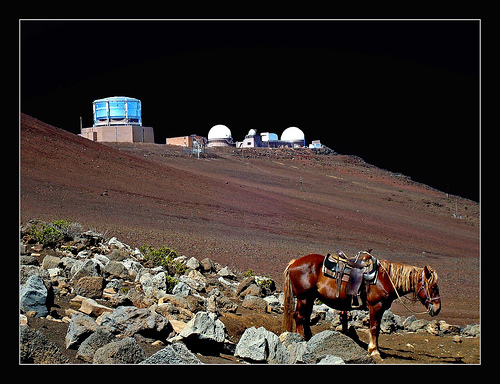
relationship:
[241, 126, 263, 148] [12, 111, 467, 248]
building on dirt hill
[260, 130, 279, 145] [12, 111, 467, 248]
building on dirt hill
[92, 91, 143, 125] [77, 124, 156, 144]
boiler on building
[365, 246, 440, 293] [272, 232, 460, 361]
blonde hair on horse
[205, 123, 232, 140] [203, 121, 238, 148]
globe on buildings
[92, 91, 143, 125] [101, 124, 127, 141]
boiler on building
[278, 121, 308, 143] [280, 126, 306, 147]
globe on buildings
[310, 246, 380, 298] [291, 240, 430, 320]
saddle on horse's back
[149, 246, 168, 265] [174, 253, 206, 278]
bushes in rocks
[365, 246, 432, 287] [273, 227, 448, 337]
blonde hair on horse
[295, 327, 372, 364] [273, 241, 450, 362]
rock surrounding horse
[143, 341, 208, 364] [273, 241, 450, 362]
rock surrounding horse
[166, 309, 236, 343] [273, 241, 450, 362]
rock surrounding horse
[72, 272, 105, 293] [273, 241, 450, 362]
rock surrounding horse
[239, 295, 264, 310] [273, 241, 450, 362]
rock surrounding horse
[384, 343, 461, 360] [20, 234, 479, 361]
shadow on ground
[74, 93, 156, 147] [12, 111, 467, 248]
buildings on dirt hill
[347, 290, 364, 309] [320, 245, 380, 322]
stirrups on saddle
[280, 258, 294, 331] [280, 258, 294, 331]
tail on tail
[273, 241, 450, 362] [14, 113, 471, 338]
horse on hill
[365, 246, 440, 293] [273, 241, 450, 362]
blonde hair on horse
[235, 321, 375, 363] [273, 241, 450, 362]
rocks beside horse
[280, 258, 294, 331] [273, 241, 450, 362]
tail on horse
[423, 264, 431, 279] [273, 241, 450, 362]
ear on horse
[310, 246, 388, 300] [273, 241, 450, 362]
saddle on horse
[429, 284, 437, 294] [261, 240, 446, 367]
eye on horse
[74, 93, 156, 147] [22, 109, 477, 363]
buildings on hill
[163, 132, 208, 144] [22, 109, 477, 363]
buildings on hill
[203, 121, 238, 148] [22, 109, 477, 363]
buildings on hill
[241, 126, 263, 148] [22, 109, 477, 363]
building on hill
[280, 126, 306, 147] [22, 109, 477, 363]
buildings on hill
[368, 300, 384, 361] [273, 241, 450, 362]
leg on horse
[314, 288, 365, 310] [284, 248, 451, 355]
stomach on horse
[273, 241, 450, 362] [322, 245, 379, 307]
horse wearing saddle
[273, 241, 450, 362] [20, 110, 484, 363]
horse looking at ground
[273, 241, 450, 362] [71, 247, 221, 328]
horse standing rocks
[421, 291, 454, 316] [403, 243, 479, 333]
harness around face